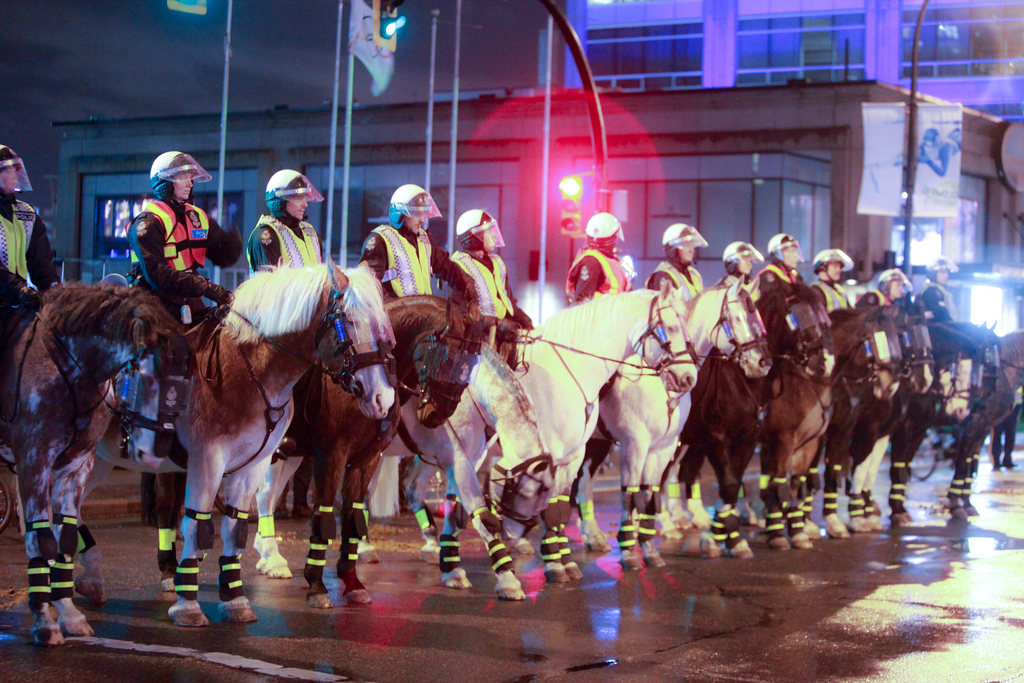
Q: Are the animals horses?
A: Yes, all the animals are horses.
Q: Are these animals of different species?
A: No, all the animals are horses.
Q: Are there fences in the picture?
A: No, there are no fences.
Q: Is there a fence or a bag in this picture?
A: No, there are no fences or bags.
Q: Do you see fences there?
A: No, there are no fences.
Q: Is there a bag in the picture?
A: No, there are no bags.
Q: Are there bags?
A: No, there are no bags.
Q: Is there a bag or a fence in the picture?
A: No, there are no bags or fences.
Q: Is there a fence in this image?
A: No, there are no fences.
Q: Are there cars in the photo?
A: No, there are no cars.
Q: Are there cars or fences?
A: No, there are no cars or fences.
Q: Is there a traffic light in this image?
A: Yes, there is a traffic light.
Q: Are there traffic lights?
A: Yes, there is a traffic light.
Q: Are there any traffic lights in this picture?
A: Yes, there is a traffic light.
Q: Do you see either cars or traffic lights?
A: Yes, there is a traffic light.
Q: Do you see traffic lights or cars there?
A: Yes, there is a traffic light.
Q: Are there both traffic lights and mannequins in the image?
A: No, there is a traffic light but no mannequins.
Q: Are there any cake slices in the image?
A: No, there are no cake slices.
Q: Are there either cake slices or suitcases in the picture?
A: No, there are no cake slices or suitcases.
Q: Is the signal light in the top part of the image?
A: Yes, the signal light is in the top of the image.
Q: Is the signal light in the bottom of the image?
A: No, the signal light is in the top of the image.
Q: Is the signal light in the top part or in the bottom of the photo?
A: The signal light is in the top of the image.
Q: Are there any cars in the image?
A: No, there are no cars.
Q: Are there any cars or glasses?
A: No, there are no cars or glasses.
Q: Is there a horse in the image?
A: Yes, there is a horse.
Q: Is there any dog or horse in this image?
A: Yes, there is a horse.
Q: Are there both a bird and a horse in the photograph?
A: No, there is a horse but no birds.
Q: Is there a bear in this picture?
A: No, there are no bears.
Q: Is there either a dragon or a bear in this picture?
A: No, there are no bears or dragons.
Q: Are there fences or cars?
A: No, there are no fences or cars.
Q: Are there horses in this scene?
A: Yes, there is a horse.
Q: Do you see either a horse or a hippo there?
A: Yes, there is a horse.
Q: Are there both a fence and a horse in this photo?
A: No, there is a horse but no fences.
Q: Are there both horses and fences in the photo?
A: No, there is a horse but no fences.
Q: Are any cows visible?
A: No, there are no cows.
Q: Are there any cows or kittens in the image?
A: No, there are no cows or kittens.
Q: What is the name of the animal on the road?
A: The animal is a horse.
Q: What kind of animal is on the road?
A: The animal is a horse.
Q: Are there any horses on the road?
A: Yes, there is a horse on the road.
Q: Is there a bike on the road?
A: No, there is a horse on the road.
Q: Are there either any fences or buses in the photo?
A: No, there are no fences or buses.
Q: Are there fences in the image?
A: No, there are no fences.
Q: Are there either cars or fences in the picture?
A: No, there are no fences or cars.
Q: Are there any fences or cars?
A: No, there are no fences or cars.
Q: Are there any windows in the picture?
A: Yes, there are windows.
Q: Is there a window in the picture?
A: Yes, there are windows.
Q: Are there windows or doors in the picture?
A: Yes, there are windows.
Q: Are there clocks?
A: No, there are no clocks.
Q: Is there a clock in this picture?
A: No, there are no clocks.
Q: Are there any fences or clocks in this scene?
A: No, there are no clocks or fences.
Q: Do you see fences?
A: No, there are no fences.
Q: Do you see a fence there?
A: No, there are no fences.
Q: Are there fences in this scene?
A: No, there are no fences.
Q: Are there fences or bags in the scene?
A: No, there are no fences or bags.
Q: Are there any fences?
A: No, there are no fences.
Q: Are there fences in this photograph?
A: No, there are no fences.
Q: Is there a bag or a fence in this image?
A: No, there are no fences or bags.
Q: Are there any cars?
A: No, there are no cars.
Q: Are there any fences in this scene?
A: No, there are no fences.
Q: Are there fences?
A: No, there are no fences.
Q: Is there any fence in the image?
A: No, there are no fences.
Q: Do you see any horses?
A: Yes, there is a horse.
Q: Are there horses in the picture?
A: Yes, there is a horse.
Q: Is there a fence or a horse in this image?
A: Yes, there is a horse.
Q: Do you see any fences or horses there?
A: Yes, there is a horse.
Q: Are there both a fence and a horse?
A: No, there is a horse but no fences.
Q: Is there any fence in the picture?
A: No, there are no fences.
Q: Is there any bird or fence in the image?
A: No, there are no fences or birds.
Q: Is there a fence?
A: No, there are no fences.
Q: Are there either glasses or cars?
A: No, there are no cars or glasses.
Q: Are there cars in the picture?
A: No, there are no cars.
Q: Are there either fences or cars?
A: No, there are no cars or fences.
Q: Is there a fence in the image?
A: No, there are no fences.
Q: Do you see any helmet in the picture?
A: Yes, there is a helmet.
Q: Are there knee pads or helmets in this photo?
A: Yes, there is a helmet.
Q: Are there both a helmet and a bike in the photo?
A: No, there is a helmet but no bikes.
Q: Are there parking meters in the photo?
A: No, there are no parking meters.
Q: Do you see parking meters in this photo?
A: No, there are no parking meters.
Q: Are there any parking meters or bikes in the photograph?
A: No, there are no parking meters or bikes.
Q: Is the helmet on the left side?
A: Yes, the helmet is on the left of the image.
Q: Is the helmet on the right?
A: No, the helmet is on the left of the image.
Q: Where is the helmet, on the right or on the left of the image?
A: The helmet is on the left of the image.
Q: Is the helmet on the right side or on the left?
A: The helmet is on the left of the image.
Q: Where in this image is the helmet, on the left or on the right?
A: The helmet is on the left of the image.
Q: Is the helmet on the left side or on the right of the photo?
A: The helmet is on the left of the image.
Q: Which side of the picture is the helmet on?
A: The helmet is on the left of the image.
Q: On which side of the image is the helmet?
A: The helmet is on the left of the image.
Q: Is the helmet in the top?
A: Yes, the helmet is in the top of the image.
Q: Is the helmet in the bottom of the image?
A: No, the helmet is in the top of the image.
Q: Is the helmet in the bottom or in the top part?
A: The helmet is in the top of the image.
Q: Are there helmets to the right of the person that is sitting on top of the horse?
A: Yes, there is a helmet to the right of the person.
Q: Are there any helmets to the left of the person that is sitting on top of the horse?
A: No, the helmet is to the right of the person.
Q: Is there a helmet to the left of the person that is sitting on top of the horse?
A: No, the helmet is to the right of the person.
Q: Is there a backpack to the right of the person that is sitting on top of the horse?
A: No, there is a helmet to the right of the person.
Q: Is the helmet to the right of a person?
A: Yes, the helmet is to the right of a person.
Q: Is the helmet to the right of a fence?
A: No, the helmet is to the right of a person.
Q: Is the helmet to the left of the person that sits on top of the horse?
A: No, the helmet is to the right of the person.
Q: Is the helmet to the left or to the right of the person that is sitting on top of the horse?
A: The helmet is to the right of the person.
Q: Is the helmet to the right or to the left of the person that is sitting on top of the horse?
A: The helmet is to the right of the person.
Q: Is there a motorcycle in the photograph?
A: No, there are no motorcycles.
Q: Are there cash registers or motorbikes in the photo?
A: No, there are no motorbikes or cash registers.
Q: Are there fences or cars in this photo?
A: No, there are no cars or fences.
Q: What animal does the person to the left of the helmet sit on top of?
A: The person sits on top of the horse.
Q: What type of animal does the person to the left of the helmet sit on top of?
A: The person sits on top of the horse.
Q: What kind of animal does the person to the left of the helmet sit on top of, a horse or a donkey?
A: The person sits on top of a horse.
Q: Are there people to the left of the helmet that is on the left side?
A: Yes, there is a person to the left of the helmet.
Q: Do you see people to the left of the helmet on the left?
A: Yes, there is a person to the left of the helmet.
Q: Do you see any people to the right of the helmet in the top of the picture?
A: No, the person is to the left of the helmet.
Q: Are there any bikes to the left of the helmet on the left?
A: No, there is a person to the left of the helmet.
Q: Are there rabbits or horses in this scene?
A: Yes, there is a horse.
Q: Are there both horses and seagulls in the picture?
A: No, there is a horse but no seagulls.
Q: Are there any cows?
A: No, there are no cows.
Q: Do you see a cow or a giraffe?
A: No, there are no cows or giraffes.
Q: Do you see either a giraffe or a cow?
A: No, there are no cows or giraffes.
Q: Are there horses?
A: Yes, there is a horse.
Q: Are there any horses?
A: Yes, there is a horse.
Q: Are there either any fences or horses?
A: Yes, there is a horse.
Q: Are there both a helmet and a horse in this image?
A: Yes, there are both a horse and a helmet.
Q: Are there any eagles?
A: No, there are no eagles.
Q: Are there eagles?
A: No, there are no eagles.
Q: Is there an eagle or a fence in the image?
A: No, there are no eagles or fences.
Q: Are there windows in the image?
A: Yes, there are windows.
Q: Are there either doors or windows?
A: Yes, there are windows.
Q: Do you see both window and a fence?
A: No, there are windows but no fences.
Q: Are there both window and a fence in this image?
A: No, there are windows but no fences.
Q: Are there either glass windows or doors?
A: Yes, there are glass windows.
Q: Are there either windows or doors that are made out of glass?
A: Yes, the windows are made of glass.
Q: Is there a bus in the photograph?
A: No, there are no buses.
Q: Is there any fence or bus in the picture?
A: No, there are no buses or fences.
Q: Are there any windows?
A: Yes, there are windows.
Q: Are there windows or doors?
A: Yes, there are windows.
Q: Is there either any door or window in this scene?
A: Yes, there are windows.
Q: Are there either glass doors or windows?
A: Yes, there are glass windows.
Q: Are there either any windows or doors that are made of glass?
A: Yes, the windows are made of glass.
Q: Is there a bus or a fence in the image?
A: No, there are no fences or buses.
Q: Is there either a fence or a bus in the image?
A: No, there are no fences or buses.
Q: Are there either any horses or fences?
A: Yes, there is a horse.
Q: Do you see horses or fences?
A: Yes, there is a horse.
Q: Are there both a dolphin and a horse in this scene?
A: No, there is a horse but no dolphins.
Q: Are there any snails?
A: No, there are no snails.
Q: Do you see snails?
A: No, there are no snails.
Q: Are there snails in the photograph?
A: No, there are no snails.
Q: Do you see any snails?
A: No, there are no snails.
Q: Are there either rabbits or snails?
A: No, there are no snails or rabbits.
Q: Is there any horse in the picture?
A: Yes, there is a horse.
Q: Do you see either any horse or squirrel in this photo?
A: Yes, there is a horse.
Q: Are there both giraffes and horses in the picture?
A: No, there is a horse but no giraffes.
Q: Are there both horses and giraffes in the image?
A: No, there is a horse but no giraffes.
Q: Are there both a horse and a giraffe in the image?
A: No, there is a horse but no giraffes.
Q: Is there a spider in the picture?
A: No, there are no spiders.